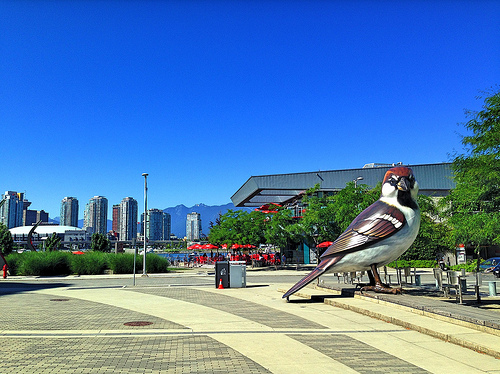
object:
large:
[284, 167, 417, 304]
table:
[189, 253, 207, 260]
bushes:
[5, 249, 64, 277]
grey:
[416, 165, 454, 187]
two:
[215, 259, 250, 288]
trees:
[440, 89, 495, 292]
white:
[219, 281, 222, 285]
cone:
[217, 278, 225, 289]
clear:
[1, 1, 500, 225]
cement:
[0, 277, 499, 372]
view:
[48, 204, 308, 285]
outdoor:
[0, 5, 499, 371]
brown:
[355, 210, 375, 238]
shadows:
[0, 282, 70, 298]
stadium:
[2, 224, 88, 252]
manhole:
[123, 319, 154, 328]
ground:
[0, 287, 443, 372]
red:
[2, 264, 7, 277]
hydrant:
[1, 264, 7, 279]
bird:
[281, 165, 423, 303]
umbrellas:
[201, 243, 219, 249]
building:
[229, 155, 500, 270]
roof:
[230, 161, 500, 208]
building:
[0, 188, 25, 238]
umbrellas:
[185, 242, 204, 250]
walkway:
[1, 257, 496, 371]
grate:
[123, 320, 154, 327]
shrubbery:
[66, 249, 108, 276]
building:
[118, 196, 141, 248]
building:
[60, 196, 78, 229]